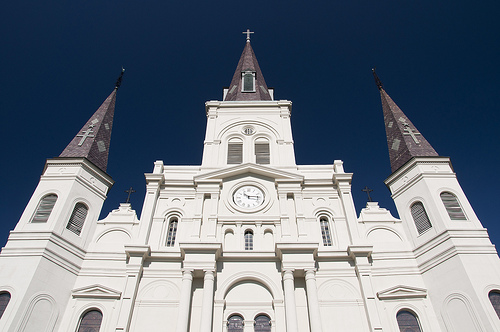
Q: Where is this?
A: This is at the church.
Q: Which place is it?
A: It is a church.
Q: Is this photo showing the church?
A: Yes, it is showing the church.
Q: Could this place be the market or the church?
A: It is the church.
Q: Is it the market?
A: No, it is the church.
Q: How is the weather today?
A: It is cloudless.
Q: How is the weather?
A: It is cloudless.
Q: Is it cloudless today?
A: Yes, it is cloudless.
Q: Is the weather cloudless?
A: Yes, it is cloudless.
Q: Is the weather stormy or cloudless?
A: It is cloudless.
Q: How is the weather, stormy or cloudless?
A: It is cloudless.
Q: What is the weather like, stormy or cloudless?
A: It is cloudless.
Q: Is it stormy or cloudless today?
A: It is cloudless.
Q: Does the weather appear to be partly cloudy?
A: No, it is cloudless.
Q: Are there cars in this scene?
A: No, there are no cars.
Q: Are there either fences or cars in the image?
A: No, there are no cars or fences.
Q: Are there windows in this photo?
A: Yes, there is a window.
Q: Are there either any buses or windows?
A: Yes, there is a window.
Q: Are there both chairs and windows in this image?
A: No, there is a window but no chairs.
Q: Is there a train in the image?
A: No, there are no trains.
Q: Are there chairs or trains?
A: No, there are no trains or chairs.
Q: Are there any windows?
A: Yes, there is a window.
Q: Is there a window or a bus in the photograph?
A: Yes, there is a window.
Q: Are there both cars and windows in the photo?
A: No, there is a window but no cars.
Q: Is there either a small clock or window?
A: Yes, there is a small window.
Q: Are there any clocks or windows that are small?
A: Yes, the window is small.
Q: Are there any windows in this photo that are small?
A: Yes, there is a small window.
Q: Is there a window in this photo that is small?
A: Yes, there is a window that is small.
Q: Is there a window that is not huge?
A: Yes, there is a small window.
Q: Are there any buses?
A: No, there are no buses.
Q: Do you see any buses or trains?
A: No, there are no buses or trains.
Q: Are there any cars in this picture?
A: No, there are no cars.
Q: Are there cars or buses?
A: No, there are no cars or buses.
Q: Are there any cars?
A: No, there are no cars.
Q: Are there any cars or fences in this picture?
A: No, there are no cars or fences.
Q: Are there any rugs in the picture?
A: No, there are no rugs.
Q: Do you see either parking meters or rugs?
A: No, there are no rugs or parking meters.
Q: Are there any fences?
A: No, there are no fences.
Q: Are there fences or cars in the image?
A: No, there are no fences or cars.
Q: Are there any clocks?
A: Yes, there is a clock.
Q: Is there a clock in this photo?
A: Yes, there is a clock.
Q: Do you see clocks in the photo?
A: Yes, there is a clock.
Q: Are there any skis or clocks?
A: Yes, there is a clock.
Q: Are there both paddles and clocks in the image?
A: No, there is a clock but no paddles.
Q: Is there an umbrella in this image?
A: No, there are no umbrellas.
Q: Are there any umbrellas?
A: No, there are no umbrellas.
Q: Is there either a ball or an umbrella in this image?
A: No, there are no umbrellas or balls.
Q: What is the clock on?
A: The clock is on the building.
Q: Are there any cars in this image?
A: No, there are no cars.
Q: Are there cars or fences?
A: No, there are no cars or fences.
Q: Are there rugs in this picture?
A: No, there are no rugs.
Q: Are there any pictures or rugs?
A: No, there are no rugs or pictures.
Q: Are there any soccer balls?
A: No, there are no soccer balls.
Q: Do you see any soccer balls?
A: No, there are no soccer balls.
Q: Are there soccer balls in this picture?
A: No, there are no soccer balls.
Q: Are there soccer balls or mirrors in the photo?
A: No, there are no soccer balls or mirrors.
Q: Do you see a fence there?
A: No, there are no fences.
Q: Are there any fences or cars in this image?
A: No, there are no fences or cars.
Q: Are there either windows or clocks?
A: Yes, there is a window.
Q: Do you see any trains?
A: No, there are no trains.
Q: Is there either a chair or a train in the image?
A: No, there are no trains or chairs.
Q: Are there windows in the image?
A: Yes, there is a window.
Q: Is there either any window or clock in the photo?
A: Yes, there is a window.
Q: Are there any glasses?
A: No, there are no glasses.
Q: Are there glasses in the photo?
A: No, there are no glasses.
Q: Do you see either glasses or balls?
A: No, there are no glasses or balls.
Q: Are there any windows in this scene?
A: Yes, there is a window.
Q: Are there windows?
A: Yes, there is a window.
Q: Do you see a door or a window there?
A: Yes, there is a window.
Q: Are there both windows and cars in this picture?
A: No, there is a window but no cars.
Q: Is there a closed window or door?
A: Yes, there is a closed window.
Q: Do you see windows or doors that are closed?
A: Yes, the window is closed.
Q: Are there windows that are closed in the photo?
A: Yes, there is a closed window.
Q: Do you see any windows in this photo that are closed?
A: Yes, there is a window that is closed.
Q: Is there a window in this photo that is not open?
A: Yes, there is an closed window.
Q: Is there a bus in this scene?
A: No, there are no buses.